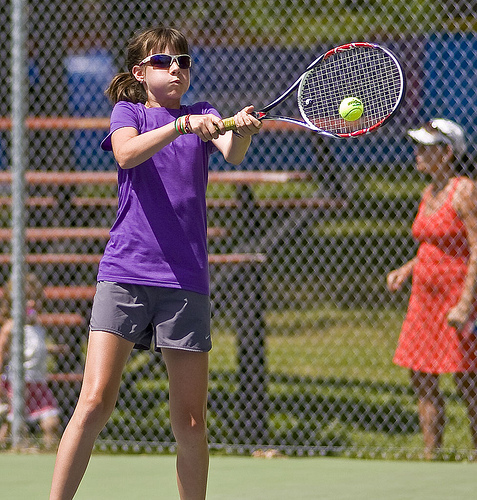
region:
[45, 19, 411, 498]
A person playing tennis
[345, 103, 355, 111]
Part of the green ball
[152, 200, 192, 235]
Part of the purple shirt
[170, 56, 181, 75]
The nose of the person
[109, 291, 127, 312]
Part of the shorts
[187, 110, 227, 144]
The right hand of he person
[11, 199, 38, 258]
Part of the fence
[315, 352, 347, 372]
Part of the grass in distance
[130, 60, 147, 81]
The right ear of the person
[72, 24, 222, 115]
little girl with long dark hair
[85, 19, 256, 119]
little girl wearing sunglasses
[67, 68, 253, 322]
little girl wearing purple short sleeve shirt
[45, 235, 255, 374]
little girl wering blue shorts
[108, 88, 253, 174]
little girl wearing hair bands on her wrist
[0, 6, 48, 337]
metal fence post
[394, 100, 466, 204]
woman wearing white hat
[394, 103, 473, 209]
woman with brown sunglasses on her head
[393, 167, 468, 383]
woman wearing melon color sun dress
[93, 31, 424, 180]
girl swinging a tennis racquet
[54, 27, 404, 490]
girl playing tennis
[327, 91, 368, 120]
yellow tennis ball hitting racket strings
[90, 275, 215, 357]
dark blue Nike shorts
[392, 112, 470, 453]
woman wearing red dress behind fence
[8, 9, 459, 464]
metal chain link fence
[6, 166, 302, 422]
red bleachers behind fence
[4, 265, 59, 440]
person walking in white shirt with pink shorts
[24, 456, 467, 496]
green tennis court surface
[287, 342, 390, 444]
green grass behind fence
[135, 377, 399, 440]
shadows cast by bleachers on grass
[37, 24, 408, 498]
A girl playing tennis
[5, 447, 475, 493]
A tennis court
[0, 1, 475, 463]
A grey chainlink fence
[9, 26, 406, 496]
A girl swinging a tennis racket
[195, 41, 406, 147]
A red and black tennis racket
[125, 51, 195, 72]
A pair of sunglasses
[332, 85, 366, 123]
A green tennis ball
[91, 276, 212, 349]
A grey pair of sports shorts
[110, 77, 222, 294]
A purple short sleeve shirt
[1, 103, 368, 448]
Wooden bleachers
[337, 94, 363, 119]
a green tennis ball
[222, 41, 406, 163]
a large tennis racket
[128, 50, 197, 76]
a girl's sunglasses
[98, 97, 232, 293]
a girl's purple shirt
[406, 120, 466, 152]
a white baseball cap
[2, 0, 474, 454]
part of a chain link fence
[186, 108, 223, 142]
the hand of a girl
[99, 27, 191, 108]
a girl's brown hair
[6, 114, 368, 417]
part of a stadium bleacher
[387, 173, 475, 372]
a woman's orange dress